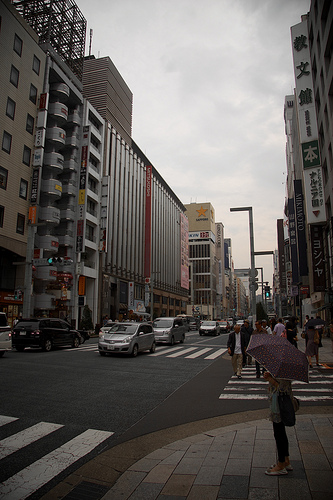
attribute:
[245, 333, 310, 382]
umbrella — purple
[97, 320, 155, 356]
car — Silver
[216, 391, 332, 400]
line — white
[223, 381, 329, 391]
line — white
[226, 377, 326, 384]
line — white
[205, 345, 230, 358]
line — white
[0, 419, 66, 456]
line — white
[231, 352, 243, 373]
pants — beige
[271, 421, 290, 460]
pants — black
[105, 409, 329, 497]
bricks — gray, red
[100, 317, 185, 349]
cars — SILVER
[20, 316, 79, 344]
van — BLACK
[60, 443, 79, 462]
lines — WHITE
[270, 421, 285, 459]
pants — BLACK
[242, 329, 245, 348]
coat — SPORT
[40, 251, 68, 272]
signal — TRAFFIC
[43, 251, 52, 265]
light — GREEN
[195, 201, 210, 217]
star — YELLOW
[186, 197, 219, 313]
building — SIDE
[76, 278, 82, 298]
sign — ORANGE, BLACK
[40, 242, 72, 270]
light — TRAFFIC, GREEN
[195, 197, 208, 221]
star — ORANGE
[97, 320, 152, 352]
vehicle — SILVER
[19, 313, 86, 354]
vehicle — BLACK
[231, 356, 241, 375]
pants — KHAKI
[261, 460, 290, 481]
shoes — FLAT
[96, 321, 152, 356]
suv — SILVER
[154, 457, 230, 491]
tiles — STONE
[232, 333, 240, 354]
shirt — WHITE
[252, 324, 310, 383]
umbrella — PURPLE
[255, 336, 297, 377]
umbrella — PURPLE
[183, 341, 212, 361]
line — white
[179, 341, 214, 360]
line — white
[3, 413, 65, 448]
line — white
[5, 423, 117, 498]
line — white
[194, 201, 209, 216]
star — red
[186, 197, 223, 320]
building — beige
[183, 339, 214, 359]
lines — big, white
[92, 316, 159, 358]
car — silver, small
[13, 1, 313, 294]
sky — grey, white